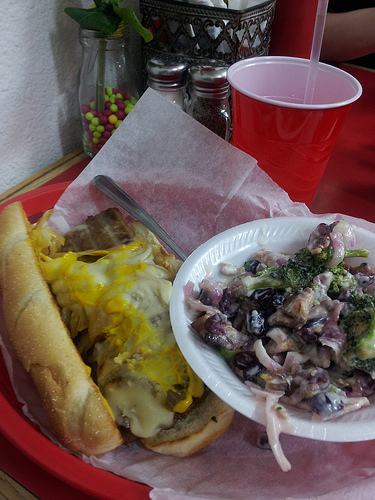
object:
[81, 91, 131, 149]
object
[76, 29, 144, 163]
vase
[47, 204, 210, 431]
meat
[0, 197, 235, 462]
sandwich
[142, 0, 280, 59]
holder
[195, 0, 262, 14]
napkin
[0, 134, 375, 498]
basket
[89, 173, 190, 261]
utensil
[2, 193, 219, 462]
hot dog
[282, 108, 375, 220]
ground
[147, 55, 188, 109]
salt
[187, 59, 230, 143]
pepper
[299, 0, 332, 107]
straw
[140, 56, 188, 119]
shaker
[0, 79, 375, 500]
table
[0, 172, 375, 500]
plate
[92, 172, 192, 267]
handle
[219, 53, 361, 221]
cup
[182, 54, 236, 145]
pepper shaker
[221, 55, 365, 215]
container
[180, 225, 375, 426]
cat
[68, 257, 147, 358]
mustard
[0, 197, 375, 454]
food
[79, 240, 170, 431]
cheese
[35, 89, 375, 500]
paper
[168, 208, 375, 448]
bowl